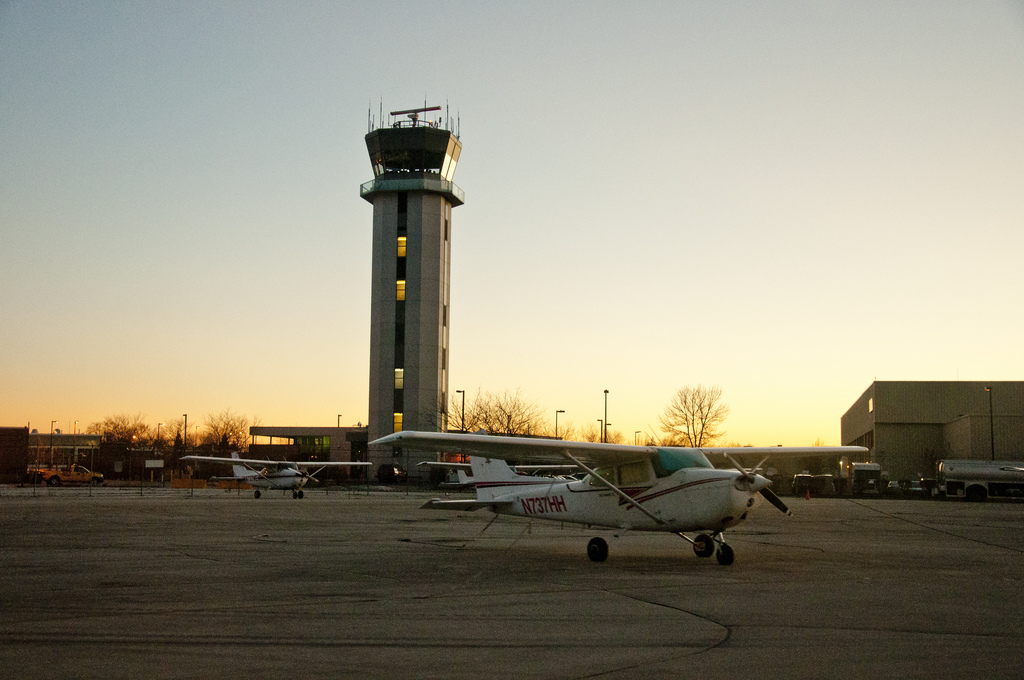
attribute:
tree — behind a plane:
[664, 377, 732, 462]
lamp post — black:
[439, 376, 472, 435]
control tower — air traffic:
[355, 93, 479, 483]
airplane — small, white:
[359, 400, 887, 595]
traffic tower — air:
[355, 89, 466, 463]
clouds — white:
[475, 27, 890, 321]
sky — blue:
[4, 9, 987, 351]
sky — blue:
[11, 5, 973, 440]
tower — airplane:
[339, 99, 489, 488]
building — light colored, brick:
[838, 361, 1022, 489]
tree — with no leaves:
[674, 378, 722, 456]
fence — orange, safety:
[159, 461, 248, 500]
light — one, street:
[593, 378, 622, 450]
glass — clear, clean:
[375, 229, 427, 258]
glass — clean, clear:
[375, 359, 408, 399]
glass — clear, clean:
[636, 437, 714, 500]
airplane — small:
[369, 430, 871, 565]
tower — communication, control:
[353, 85, 468, 490]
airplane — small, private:
[361, 418, 874, 565]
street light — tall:
[590, 376, 616, 443]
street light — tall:
[586, 373, 619, 443]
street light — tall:
[449, 380, 467, 439]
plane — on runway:
[337, 417, 798, 573]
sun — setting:
[24, 362, 820, 455]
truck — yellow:
[24, 447, 102, 484]